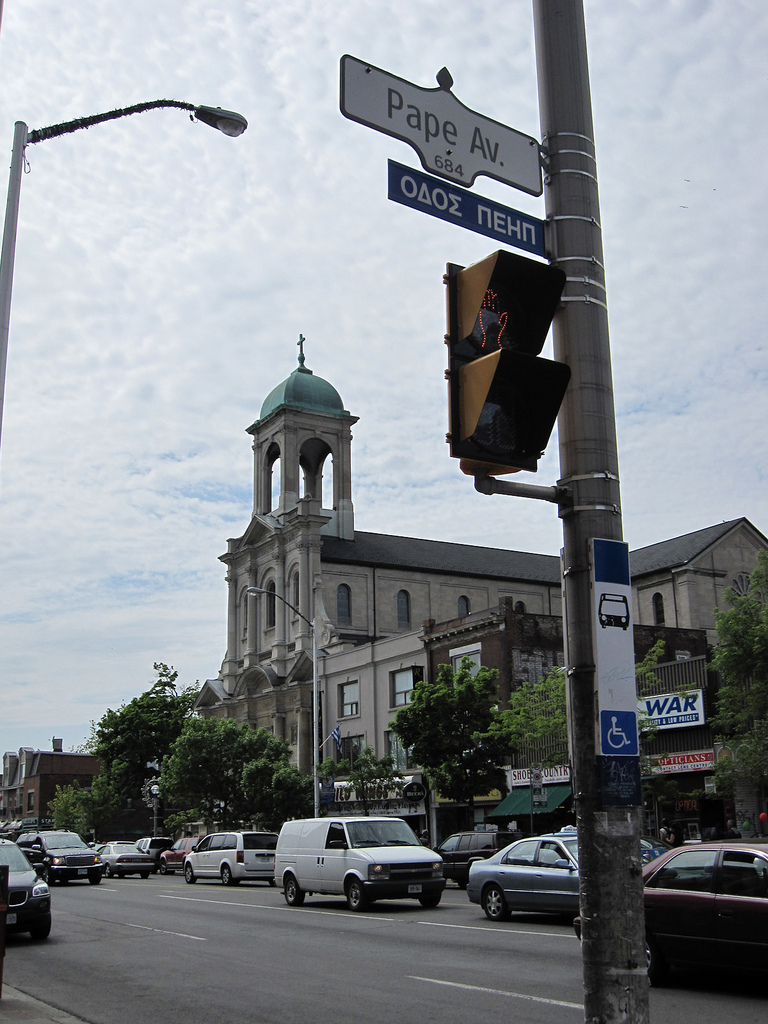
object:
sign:
[338, 55, 544, 202]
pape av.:
[388, 87, 504, 167]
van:
[184, 833, 279, 887]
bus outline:
[599, 592, 630, 630]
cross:
[297, 334, 305, 354]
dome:
[260, 372, 350, 419]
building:
[191, 336, 766, 853]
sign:
[388, 158, 548, 257]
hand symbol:
[480, 288, 508, 349]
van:
[274, 818, 447, 913]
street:
[0, 870, 768, 1024]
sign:
[587, 537, 639, 761]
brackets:
[544, 169, 598, 185]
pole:
[532, 0, 654, 1024]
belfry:
[245, 332, 361, 538]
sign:
[512, 764, 570, 786]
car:
[467, 837, 602, 922]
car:
[434, 830, 523, 890]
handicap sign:
[607, 715, 629, 747]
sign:
[637, 688, 706, 731]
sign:
[640, 750, 714, 777]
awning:
[484, 783, 571, 819]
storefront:
[483, 758, 576, 865]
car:
[574, 844, 768, 991]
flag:
[331, 725, 343, 753]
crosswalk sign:
[442, 249, 572, 476]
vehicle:
[15, 830, 102, 885]